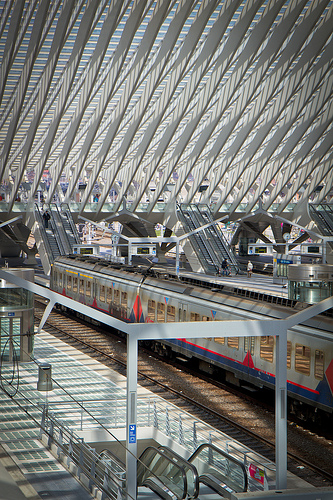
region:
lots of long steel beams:
[44, 6, 323, 208]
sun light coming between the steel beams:
[41, 7, 285, 206]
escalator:
[148, 438, 257, 498]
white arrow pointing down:
[125, 418, 149, 456]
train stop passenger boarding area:
[24, 241, 317, 455]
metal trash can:
[35, 361, 63, 396]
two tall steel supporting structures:
[119, 318, 316, 498]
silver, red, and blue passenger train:
[47, 256, 202, 358]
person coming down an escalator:
[171, 200, 269, 277]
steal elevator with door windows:
[2, 267, 50, 368]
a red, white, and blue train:
[57, 254, 331, 411]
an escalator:
[31, 202, 89, 272]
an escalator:
[174, 205, 243, 276]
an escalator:
[306, 199, 332, 247]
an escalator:
[68, 435, 248, 498]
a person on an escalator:
[40, 205, 54, 229]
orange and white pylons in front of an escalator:
[214, 265, 234, 276]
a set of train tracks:
[12, 284, 332, 491]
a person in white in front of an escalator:
[243, 258, 257, 281]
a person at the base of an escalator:
[213, 252, 232, 279]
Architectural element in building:
[8, 18, 328, 202]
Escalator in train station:
[22, 197, 261, 273]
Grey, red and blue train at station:
[36, 244, 324, 402]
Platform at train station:
[22, 326, 183, 427]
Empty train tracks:
[60, 308, 307, 480]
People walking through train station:
[205, 249, 260, 278]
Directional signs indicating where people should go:
[122, 420, 148, 458]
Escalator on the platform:
[112, 417, 250, 490]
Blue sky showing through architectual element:
[27, 6, 301, 133]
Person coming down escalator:
[31, 192, 86, 247]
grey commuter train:
[66, 254, 281, 377]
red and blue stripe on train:
[169, 314, 330, 391]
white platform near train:
[28, 358, 194, 452]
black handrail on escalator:
[146, 442, 195, 498]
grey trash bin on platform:
[26, 358, 75, 408]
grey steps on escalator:
[40, 217, 65, 269]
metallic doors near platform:
[0, 288, 52, 356]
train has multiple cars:
[65, 256, 324, 400]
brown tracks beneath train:
[53, 325, 262, 458]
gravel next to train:
[81, 333, 268, 438]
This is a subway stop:
[13, 16, 326, 489]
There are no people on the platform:
[4, 290, 232, 492]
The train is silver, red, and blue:
[40, 241, 331, 414]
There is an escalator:
[100, 434, 219, 498]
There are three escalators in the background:
[7, 182, 331, 290]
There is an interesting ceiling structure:
[5, 5, 328, 222]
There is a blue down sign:
[118, 406, 146, 454]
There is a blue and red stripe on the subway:
[47, 280, 331, 413]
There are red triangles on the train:
[43, 262, 325, 383]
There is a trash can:
[19, 356, 67, 394]